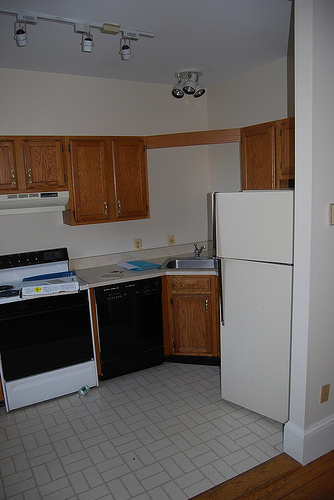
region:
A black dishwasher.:
[93, 276, 160, 378]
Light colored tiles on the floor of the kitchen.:
[0, 360, 280, 493]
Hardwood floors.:
[188, 449, 328, 494]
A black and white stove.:
[0, 245, 98, 407]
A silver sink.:
[161, 243, 217, 271]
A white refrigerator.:
[210, 190, 291, 423]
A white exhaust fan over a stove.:
[0, 192, 68, 213]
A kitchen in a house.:
[3, 77, 304, 492]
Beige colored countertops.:
[69, 240, 221, 286]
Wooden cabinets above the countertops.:
[0, 118, 302, 224]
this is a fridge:
[206, 182, 301, 399]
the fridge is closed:
[217, 255, 261, 334]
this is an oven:
[0, 300, 90, 397]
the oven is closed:
[0, 313, 82, 390]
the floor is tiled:
[110, 380, 206, 469]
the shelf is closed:
[85, 156, 141, 213]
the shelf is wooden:
[81, 151, 139, 209]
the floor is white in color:
[101, 394, 207, 467]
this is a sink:
[177, 258, 205, 268]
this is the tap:
[192, 242, 206, 254]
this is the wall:
[191, 20, 225, 40]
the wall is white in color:
[207, 6, 248, 45]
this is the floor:
[149, 373, 205, 410]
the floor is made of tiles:
[105, 411, 147, 450]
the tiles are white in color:
[71, 397, 188, 478]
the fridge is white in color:
[240, 275, 269, 372]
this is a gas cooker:
[5, 252, 94, 389]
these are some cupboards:
[74, 147, 147, 223]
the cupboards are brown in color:
[100, 153, 123, 171]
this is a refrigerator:
[201, 182, 297, 427]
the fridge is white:
[203, 184, 302, 429]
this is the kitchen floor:
[0, 358, 292, 498]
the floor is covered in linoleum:
[0, 358, 288, 496]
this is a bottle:
[75, 382, 97, 402]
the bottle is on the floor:
[70, 380, 94, 401]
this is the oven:
[0, 238, 101, 420]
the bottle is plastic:
[74, 381, 94, 402]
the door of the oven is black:
[0, 283, 96, 386]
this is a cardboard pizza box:
[14, 263, 88, 296]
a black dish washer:
[92, 269, 169, 385]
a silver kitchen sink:
[156, 253, 224, 270]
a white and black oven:
[0, 245, 101, 417]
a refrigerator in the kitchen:
[210, 186, 293, 430]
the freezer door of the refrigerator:
[209, 186, 299, 260]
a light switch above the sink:
[164, 231, 177, 248]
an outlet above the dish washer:
[130, 234, 143, 253]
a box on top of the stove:
[16, 265, 81, 300]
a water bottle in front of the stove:
[71, 381, 93, 403]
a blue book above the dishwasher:
[115, 257, 163, 273]